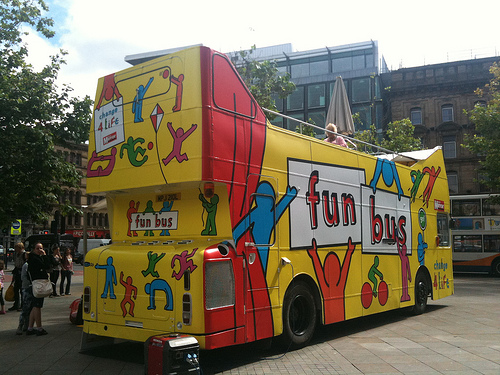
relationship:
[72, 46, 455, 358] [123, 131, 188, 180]
bus has paint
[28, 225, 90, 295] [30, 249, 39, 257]
man has hand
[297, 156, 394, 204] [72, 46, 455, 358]
logo of bus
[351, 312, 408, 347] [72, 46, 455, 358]
road beneath bus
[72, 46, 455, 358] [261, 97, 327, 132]
bus has railing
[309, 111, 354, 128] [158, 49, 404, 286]
person on top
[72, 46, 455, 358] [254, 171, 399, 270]
bus has letter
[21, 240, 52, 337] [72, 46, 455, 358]
woman next to bus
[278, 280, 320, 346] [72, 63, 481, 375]
wheel of bus